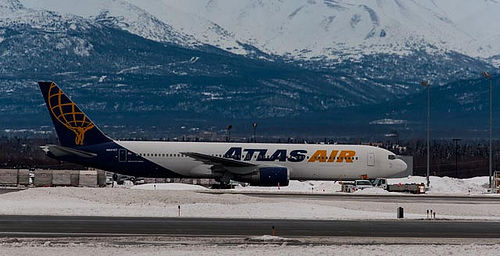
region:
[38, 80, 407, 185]
Atlas Air airplane in the snow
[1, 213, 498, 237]
cold icy runway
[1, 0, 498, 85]
snow capped mountains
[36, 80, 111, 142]
dark blue airplane tail with atlas logo on it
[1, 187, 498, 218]
dirty snow drifts on the runway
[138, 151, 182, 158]
oval windows on the side of the airplane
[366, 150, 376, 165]
closed white door on the airplane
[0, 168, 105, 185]
covered luggage carts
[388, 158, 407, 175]
white nose of the airplane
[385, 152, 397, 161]
dark tinted cockpit window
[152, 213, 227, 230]
this is the runway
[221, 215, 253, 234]
the runway is black in color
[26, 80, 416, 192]
this is an airplane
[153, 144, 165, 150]
the airplane is white in color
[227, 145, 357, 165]
these are some writings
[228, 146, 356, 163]
the writings are in bold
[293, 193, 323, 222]
this is the snow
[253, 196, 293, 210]
the snow is white in color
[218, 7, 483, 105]
this is a mountain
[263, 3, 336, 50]
the mountain is full of snow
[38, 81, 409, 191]
A plain on the ground.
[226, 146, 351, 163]
A sign on the body of a plane.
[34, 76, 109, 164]
A tail of a plane.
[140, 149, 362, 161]
Windows on the side of a plane.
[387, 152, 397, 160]
Front window of a plane.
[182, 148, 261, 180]
Right wing of a plane.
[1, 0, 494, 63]
Snow covering a mountain.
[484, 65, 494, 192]
A pole.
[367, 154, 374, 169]
Door of a plane.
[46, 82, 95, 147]
A symbol on the tail of a plane.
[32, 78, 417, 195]
Atlas Air passenger air liner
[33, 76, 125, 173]
Tail of a large atlas air airplane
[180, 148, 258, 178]
Side wing of a large atlas air airplane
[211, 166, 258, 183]
Jet engine of a large atlas air airplane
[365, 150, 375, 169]
Side door of a large atlas air airplane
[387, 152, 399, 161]
Front window of a large atlas air airplane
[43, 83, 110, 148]
Atlas air logo on a large airplane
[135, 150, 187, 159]
Passenger windows of a large atlas air airplane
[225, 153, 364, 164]
Passenger windows of a large atlas air airplane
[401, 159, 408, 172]
Nose of a large atlas air airplane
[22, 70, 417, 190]
This is an a plane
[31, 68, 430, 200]
A white and black plane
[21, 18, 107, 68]
Mountain covered with snow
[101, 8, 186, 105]
Mountain covered with snow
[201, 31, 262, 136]
Mountain covered with snow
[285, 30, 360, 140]
Mountain covered with snow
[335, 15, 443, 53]
Mountain covered with snow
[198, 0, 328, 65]
Mountain covered with snow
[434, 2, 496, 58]
Mountain covered with snow